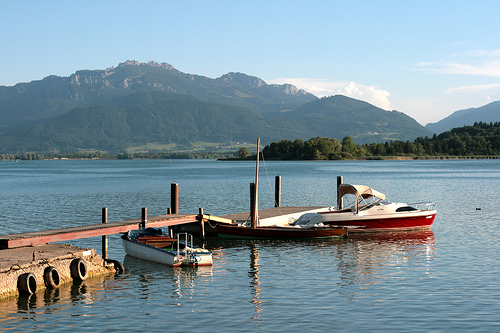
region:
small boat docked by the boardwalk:
[121, 218, 222, 282]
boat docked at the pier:
[289, 166, 454, 254]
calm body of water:
[3, 160, 497, 331]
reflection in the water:
[244, 244, 265, 281]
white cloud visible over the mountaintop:
[274, 71, 396, 116]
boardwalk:
[5, 202, 204, 249]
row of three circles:
[7, 251, 96, 296]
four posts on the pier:
[161, 163, 353, 231]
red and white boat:
[311, 176, 442, 241]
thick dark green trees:
[254, 120, 496, 162]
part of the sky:
[291, 3, 329, 26]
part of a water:
[346, 249, 414, 315]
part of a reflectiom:
[311, 228, 409, 273]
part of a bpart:
[216, 163, 328, 250]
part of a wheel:
[32, 266, 57, 293]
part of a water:
[333, 237, 361, 249]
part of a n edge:
[9, 261, 44, 287]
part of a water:
[373, 194, 474, 277]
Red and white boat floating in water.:
[343, 188, 420, 267]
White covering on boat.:
[338, 167, 388, 210]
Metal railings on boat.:
[344, 191, 378, 213]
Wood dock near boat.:
[216, 173, 328, 235]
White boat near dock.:
[121, 215, 215, 294]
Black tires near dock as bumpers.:
[14, 263, 119, 288]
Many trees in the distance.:
[303, 124, 487, 161]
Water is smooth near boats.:
[288, 260, 413, 320]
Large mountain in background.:
[53, 55, 305, 120]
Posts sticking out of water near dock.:
[92, 194, 153, 243]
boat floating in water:
[296, 185, 441, 233]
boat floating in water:
[121, 227, 211, 269]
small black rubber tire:
[71, 257, 87, 281]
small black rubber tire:
[44, 265, 62, 285]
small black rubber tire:
[20, 272, 41, 297]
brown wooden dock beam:
[138, 207, 150, 231]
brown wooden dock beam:
[101, 207, 108, 254]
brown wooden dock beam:
[171, 183, 181, 210]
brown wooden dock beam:
[248, 182, 260, 225]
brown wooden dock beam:
[273, 172, 283, 206]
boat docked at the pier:
[112, 216, 214, 276]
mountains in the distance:
[1, 46, 426, 168]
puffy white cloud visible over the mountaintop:
[278, 75, 393, 112]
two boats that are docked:
[111, 178, 456, 268]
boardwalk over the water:
[0, 189, 215, 263]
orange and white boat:
[310, 178, 442, 238]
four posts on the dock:
[160, 173, 354, 225]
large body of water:
[1, 159, 497, 328]